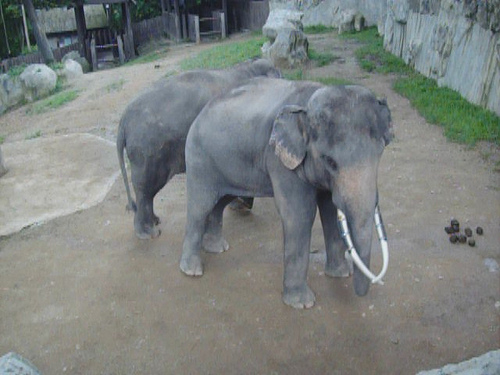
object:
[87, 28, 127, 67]
gate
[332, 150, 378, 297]
trunk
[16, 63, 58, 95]
grey boulder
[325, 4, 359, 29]
grey boulder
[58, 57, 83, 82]
grey boulder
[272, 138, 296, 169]
dirt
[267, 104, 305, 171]
ear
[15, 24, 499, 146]
grass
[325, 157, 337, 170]
eye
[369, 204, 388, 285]
tusk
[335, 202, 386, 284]
tusk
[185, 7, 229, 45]
gate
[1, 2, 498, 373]
enclosure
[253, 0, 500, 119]
rocks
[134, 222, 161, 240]
back feet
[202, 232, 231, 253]
back feet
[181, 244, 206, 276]
back feet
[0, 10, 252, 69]
fence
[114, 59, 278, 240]
elephant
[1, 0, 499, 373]
pen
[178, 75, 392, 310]
elephant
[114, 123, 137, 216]
tail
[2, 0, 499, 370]
exhibit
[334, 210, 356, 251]
brace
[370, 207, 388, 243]
brace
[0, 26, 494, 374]
ground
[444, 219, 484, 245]
dropping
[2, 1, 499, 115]
wall